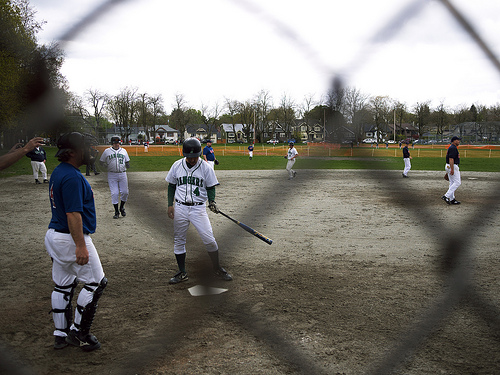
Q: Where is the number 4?
A: On the batter's jersey.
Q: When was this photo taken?
A: During a baseball game.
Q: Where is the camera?
A: Behind the chain link fence.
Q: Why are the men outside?
A: They are playing baseball.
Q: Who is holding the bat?
A: The player with a number 4.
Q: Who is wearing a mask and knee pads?
A: The baseball catcher.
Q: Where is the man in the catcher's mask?
A: To the left of the batter.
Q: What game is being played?
A: Baseball.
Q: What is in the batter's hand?
A: Bat.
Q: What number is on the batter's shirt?
A: 4.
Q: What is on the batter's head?
A: Helmet.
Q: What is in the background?
A: Buildings and trees.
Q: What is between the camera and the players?
A: Fence.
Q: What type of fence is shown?
A: Chain link.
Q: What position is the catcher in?
A: Standing.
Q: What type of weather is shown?
A: Clear.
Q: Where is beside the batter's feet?
A: Home base.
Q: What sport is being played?
A: Baseball.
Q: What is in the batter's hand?
A: Bat.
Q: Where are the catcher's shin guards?
A: Front of lower leg.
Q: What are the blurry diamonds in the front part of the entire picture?
A: Chain links.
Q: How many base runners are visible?
A: Three.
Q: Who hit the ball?
A: Player in white uniforms.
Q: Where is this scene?
A: Baseball diamond.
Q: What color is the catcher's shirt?
A: Blue.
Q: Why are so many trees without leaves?
A: Season of the year.